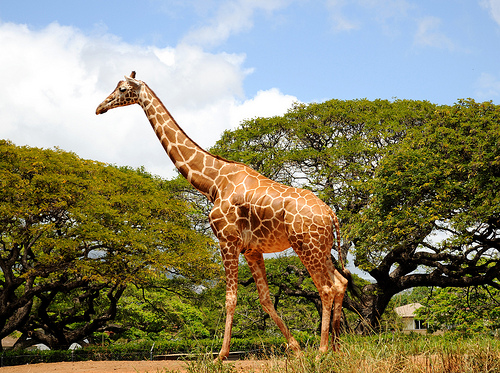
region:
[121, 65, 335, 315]
this is a giraffe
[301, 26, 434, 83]
this is the sky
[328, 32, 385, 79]
the sky is blue in color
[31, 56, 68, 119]
these are the clouds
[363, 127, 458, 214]
this is a tree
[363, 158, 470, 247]
the leaves are green in color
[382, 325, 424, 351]
this is a grass area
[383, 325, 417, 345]
the grass is green in color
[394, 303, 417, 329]
this is a house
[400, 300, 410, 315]
this is the roof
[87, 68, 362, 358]
a large giraffe facing left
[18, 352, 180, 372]
brown dirt on the floor of an enclosure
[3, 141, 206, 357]
a short wide tree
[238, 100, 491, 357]
a tall wide tree behind a giraffe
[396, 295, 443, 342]
a white and tan house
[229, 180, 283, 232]
the pattern on the giraffe's side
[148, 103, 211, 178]
the long neck of the giraffe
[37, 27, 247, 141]
billowing white clouds behind a giraffe's head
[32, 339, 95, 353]
an area of water behind the trees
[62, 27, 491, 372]
a giraffe walking in an enclosure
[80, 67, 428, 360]
A girafe near trees.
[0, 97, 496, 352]
Green trees behind the giraffe.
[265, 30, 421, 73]
Part of the sky is blue.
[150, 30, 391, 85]
Clouds in the blue sky.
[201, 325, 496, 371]
Grass near the giraffe.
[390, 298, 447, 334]
A building in the distance.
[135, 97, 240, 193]
The giraffe has a long neck.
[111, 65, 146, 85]
Horns on the giraffe.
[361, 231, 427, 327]
The trunk of a tree.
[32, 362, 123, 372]
Dirt on the ground.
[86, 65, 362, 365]
a big giraffe on a field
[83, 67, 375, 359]
giraffe has light brown spots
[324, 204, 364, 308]
long giraffe with a black turf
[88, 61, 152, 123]
a horny head of giraffe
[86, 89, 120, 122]
muzzle of giraffe is thin and long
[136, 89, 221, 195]
long neck of giraffe is sppoted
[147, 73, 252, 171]
the mane of giraffe is short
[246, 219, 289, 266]
belly of giraffe is bulky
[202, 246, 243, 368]
left feet of giraffe is forward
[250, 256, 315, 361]
right feet of giraffe is backward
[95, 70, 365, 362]
tall brown giraffe is standing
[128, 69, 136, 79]
small horn on giraffe head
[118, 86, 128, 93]
eye on giraffe head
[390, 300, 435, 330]
small white house behind tree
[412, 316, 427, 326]
window on house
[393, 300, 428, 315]
roof on house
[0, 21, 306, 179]
big white puffy cloud in a blue sky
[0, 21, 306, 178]
cloud behind giraffe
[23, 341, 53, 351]
big gray rock under tree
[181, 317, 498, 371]
tall grass in front of giraffe